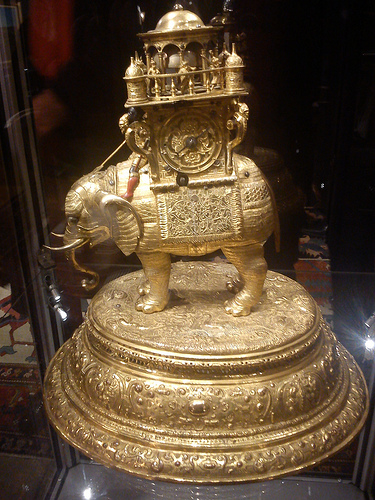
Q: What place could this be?
A: It is a museum.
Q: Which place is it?
A: It is a museum.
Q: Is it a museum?
A: Yes, it is a museum.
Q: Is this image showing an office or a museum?
A: It is showing a museum.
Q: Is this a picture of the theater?
A: No, the picture is showing the museum.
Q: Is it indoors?
A: Yes, it is indoors.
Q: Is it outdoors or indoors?
A: It is indoors.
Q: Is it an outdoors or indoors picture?
A: It is indoors.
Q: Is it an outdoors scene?
A: No, it is indoors.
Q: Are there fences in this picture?
A: No, there are no fences.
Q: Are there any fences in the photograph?
A: No, there are no fences.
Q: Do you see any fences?
A: No, there are no fences.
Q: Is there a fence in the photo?
A: No, there are no fences.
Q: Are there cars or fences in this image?
A: No, there are no fences or cars.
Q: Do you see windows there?
A: Yes, there are windows.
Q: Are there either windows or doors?
A: Yes, there are windows.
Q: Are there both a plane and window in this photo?
A: No, there are windows but no airplanes.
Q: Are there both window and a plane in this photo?
A: No, there are windows but no airplanes.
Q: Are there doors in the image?
A: No, there are no doors.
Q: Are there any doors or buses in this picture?
A: No, there are no doors or buses.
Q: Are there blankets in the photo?
A: Yes, there is a blanket.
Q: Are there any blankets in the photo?
A: Yes, there is a blanket.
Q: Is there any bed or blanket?
A: Yes, there is a blanket.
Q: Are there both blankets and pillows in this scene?
A: No, there is a blanket but no pillows.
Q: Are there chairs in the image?
A: No, there are no chairs.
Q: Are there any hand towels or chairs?
A: No, there are no chairs or hand towels.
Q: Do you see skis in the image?
A: No, there are no skis.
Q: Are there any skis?
A: No, there are no skis.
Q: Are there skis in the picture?
A: No, there are no skis.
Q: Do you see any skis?
A: No, there are no skis.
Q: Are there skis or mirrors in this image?
A: No, there are no skis or mirrors.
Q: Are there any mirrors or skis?
A: No, there are no skis or mirrors.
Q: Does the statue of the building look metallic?
A: Yes, the statue is metallic.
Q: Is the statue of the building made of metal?
A: Yes, the statue is made of metal.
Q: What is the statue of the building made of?
A: The statue is made of metal.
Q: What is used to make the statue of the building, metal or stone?
A: The statue is made of metal.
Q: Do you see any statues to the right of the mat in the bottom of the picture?
A: Yes, there is a statue to the right of the mat.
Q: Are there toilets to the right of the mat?
A: No, there is a statue to the right of the mat.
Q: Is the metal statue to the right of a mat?
A: Yes, the statue is to the right of a mat.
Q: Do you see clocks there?
A: Yes, there is a clock.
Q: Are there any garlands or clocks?
A: Yes, there is a clock.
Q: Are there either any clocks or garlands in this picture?
A: Yes, there is a clock.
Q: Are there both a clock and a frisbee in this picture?
A: No, there is a clock but no frisbees.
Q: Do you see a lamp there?
A: No, there are no lamps.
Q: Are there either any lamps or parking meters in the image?
A: No, there are no lamps or parking meters.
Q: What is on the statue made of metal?
A: The clock is on the statue.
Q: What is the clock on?
A: The clock is on the statue.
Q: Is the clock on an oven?
A: No, the clock is on the statue.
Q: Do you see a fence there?
A: No, there are no fences.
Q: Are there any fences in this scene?
A: No, there are no fences.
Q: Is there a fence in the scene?
A: No, there are no fences.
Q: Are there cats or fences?
A: No, there are no fences or cats.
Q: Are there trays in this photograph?
A: No, there are no trays.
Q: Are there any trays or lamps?
A: No, there are no trays or lamps.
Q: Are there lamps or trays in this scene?
A: No, there are no trays or lamps.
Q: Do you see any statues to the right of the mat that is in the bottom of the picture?
A: Yes, there is a statue to the right of the mat.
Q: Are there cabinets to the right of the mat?
A: No, there is a statue to the right of the mat.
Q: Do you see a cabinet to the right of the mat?
A: No, there is a statue to the right of the mat.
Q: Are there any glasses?
A: No, there are no glasses.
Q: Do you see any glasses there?
A: No, there are no glasses.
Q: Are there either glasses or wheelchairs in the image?
A: No, there are no glasses or wheelchairs.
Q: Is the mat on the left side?
A: Yes, the mat is on the left of the image.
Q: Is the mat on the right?
A: No, the mat is on the left of the image.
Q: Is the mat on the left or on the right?
A: The mat is on the left of the image.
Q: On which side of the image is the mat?
A: The mat is on the left of the image.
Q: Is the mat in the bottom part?
A: Yes, the mat is in the bottom of the image.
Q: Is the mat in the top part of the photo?
A: No, the mat is in the bottom of the image.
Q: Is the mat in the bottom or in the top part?
A: The mat is in the bottom of the image.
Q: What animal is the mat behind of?
A: The mat is behind the elephant.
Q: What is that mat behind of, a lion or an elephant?
A: The mat is behind an elephant.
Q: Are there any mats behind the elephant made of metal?
A: Yes, there is a mat behind the elephant.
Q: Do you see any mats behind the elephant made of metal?
A: Yes, there is a mat behind the elephant.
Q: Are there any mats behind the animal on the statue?
A: Yes, there is a mat behind the elephant.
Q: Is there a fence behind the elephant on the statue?
A: No, there is a mat behind the elephant.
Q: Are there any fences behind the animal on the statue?
A: No, there is a mat behind the elephant.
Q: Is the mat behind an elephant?
A: Yes, the mat is behind an elephant.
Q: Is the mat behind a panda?
A: No, the mat is behind an elephant.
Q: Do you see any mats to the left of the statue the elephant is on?
A: Yes, there is a mat to the left of the statue.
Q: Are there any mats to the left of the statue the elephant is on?
A: Yes, there is a mat to the left of the statue.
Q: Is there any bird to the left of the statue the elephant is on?
A: No, there is a mat to the left of the statue.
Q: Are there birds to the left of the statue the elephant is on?
A: No, there is a mat to the left of the statue.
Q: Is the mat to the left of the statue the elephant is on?
A: Yes, the mat is to the left of the statue.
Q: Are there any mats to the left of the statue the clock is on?
A: Yes, there is a mat to the left of the statue.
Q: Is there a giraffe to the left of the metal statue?
A: No, there is a mat to the left of the statue.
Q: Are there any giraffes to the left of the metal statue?
A: No, there is a mat to the left of the statue.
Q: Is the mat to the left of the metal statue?
A: Yes, the mat is to the left of the statue.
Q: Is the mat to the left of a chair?
A: No, the mat is to the left of the statue.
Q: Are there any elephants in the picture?
A: Yes, there is an elephant.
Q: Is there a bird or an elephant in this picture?
A: Yes, there is an elephant.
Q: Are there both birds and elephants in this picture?
A: No, there is an elephant but no birds.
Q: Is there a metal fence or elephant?
A: Yes, there is a metal elephant.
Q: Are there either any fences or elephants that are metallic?
A: Yes, the elephant is metallic.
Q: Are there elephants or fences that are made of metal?
A: Yes, the elephant is made of metal.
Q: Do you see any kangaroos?
A: No, there are no kangaroos.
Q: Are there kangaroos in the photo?
A: No, there are no kangaroos.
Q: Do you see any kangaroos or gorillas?
A: No, there are no kangaroos or gorillas.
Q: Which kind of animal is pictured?
A: The animal is an elephant.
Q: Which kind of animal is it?
A: The animal is an elephant.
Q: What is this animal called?
A: This is an elephant.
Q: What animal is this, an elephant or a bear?
A: This is an elephant.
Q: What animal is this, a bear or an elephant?
A: This is an elephant.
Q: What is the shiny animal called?
A: The animal is an elephant.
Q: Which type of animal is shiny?
A: The animal is an elephant.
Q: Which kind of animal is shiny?
A: The animal is an elephant.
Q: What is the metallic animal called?
A: The animal is an elephant.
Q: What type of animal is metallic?
A: The animal is an elephant.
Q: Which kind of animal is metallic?
A: The animal is an elephant.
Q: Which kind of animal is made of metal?
A: The animal is an elephant.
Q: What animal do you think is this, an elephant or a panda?
A: This is an elephant.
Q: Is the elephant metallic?
A: Yes, the elephant is metallic.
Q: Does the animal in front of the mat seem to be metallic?
A: Yes, the elephant is metallic.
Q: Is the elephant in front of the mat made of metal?
A: Yes, the elephant is made of metal.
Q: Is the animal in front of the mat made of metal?
A: Yes, the elephant is made of metal.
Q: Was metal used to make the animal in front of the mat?
A: Yes, the elephant is made of metal.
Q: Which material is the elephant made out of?
A: The elephant is made of metal.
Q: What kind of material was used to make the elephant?
A: The elephant is made of metal.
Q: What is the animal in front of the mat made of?
A: The elephant is made of metal.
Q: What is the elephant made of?
A: The elephant is made of metal.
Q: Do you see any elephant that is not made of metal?
A: No, there is an elephant but it is made of metal.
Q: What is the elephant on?
A: The elephant is on the statue.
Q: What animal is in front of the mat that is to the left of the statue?
A: The elephant is in front of the mat.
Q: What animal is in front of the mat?
A: The elephant is in front of the mat.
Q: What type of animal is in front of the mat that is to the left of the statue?
A: The animal is an elephant.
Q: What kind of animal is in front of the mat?
A: The animal is an elephant.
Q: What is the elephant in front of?
A: The elephant is in front of the mat.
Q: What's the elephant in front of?
A: The elephant is in front of the mat.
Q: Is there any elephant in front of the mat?
A: Yes, there is an elephant in front of the mat.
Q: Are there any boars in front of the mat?
A: No, there is an elephant in front of the mat.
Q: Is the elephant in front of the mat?
A: Yes, the elephant is in front of the mat.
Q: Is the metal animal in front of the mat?
A: Yes, the elephant is in front of the mat.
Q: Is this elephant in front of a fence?
A: No, the elephant is in front of the mat.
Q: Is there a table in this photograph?
A: Yes, there is a table.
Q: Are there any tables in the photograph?
A: Yes, there is a table.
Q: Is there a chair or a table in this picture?
A: Yes, there is a table.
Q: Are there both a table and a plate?
A: No, there is a table but no plates.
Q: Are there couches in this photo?
A: No, there are no couches.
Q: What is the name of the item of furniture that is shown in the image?
A: The piece of furniture is a table.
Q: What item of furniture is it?
A: The piece of furniture is a table.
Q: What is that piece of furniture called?
A: This is a table.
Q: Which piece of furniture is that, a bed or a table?
A: This is a table.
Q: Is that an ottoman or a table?
A: That is a table.